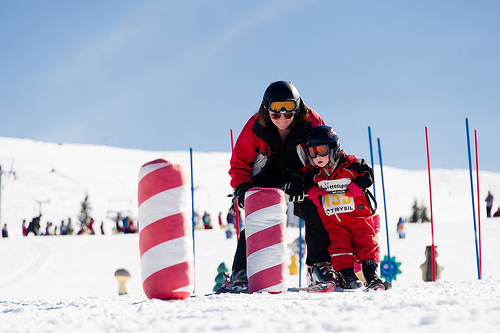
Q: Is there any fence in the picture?
A: No, there are no fences.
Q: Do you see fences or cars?
A: No, there are no fences or cars.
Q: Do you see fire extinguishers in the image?
A: No, there are no fire extinguishers.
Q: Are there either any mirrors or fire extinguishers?
A: No, there are no fire extinguishers or mirrors.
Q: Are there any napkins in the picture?
A: No, there are no napkins.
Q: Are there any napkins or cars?
A: No, there are no napkins or cars.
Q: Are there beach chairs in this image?
A: No, there are no beach chairs.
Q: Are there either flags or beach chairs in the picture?
A: No, there are no beach chairs or flags.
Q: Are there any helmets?
A: Yes, there is a helmet.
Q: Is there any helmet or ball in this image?
A: Yes, there is a helmet.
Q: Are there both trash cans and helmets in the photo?
A: No, there is a helmet but no trash cans.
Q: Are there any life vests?
A: No, there are no life vests.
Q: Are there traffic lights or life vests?
A: No, there are no life vests or traffic lights.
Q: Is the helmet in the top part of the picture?
A: Yes, the helmet is in the top of the image.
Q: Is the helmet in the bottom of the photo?
A: No, the helmet is in the top of the image.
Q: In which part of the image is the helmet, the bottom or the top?
A: The helmet is in the top of the image.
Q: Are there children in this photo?
A: Yes, there is a child.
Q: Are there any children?
A: Yes, there is a child.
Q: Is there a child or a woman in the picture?
A: Yes, there is a child.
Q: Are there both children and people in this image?
A: Yes, there are both a child and people.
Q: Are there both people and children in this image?
A: Yes, there are both a child and people.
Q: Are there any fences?
A: No, there are no fences.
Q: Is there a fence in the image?
A: No, there are no fences.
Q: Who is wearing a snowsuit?
A: The child is wearing a snowsuit.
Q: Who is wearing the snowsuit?
A: The child is wearing a snowsuit.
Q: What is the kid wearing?
A: The kid is wearing a snowsuit.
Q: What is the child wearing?
A: The kid is wearing a snowsuit.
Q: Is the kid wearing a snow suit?
A: Yes, the kid is wearing a snow suit.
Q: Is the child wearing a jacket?
A: No, the child is wearing a snow suit.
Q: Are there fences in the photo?
A: No, there are no fences.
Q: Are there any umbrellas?
A: No, there are no umbrellas.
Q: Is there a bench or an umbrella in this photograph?
A: No, there are no umbrellas or benches.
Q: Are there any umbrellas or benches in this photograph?
A: No, there are no umbrellas or benches.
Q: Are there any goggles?
A: Yes, there are goggles.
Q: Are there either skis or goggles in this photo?
A: Yes, there are goggles.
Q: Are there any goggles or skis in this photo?
A: Yes, there are goggles.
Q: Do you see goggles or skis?
A: Yes, there are goggles.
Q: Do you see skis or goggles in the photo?
A: Yes, there are goggles.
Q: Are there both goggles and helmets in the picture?
A: Yes, there are both goggles and a helmet.